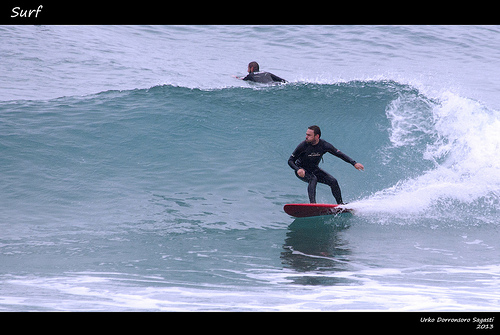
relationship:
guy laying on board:
[234, 60, 284, 89] [278, 198, 358, 219]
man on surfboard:
[280, 125, 359, 205] [278, 206, 357, 215]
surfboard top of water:
[277, 197, 354, 219] [4, 21, 499, 311]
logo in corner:
[418, 315, 496, 333] [417, 300, 484, 327]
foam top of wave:
[324, 71, 484, 221] [325, 62, 487, 252]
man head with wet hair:
[305, 125, 320, 143] [308, 126, 321, 136]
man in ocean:
[276, 112, 348, 217] [8, 37, 484, 301]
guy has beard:
[291, 120, 358, 204] [302, 139, 317, 146]